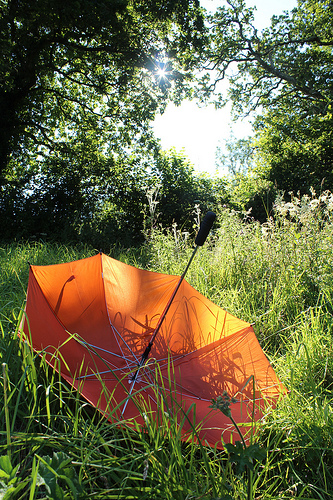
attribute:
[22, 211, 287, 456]
umbrella — open, upside down, orange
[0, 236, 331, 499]
grass — green, nice, thin, tall, high, in picture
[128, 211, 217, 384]
handle — silver, plastic, black, metal, long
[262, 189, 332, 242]
weeds — green, tall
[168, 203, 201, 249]
weeds — green, tall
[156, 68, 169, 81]
sun — bright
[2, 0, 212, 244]
trees — with many leaves, tall, with leaves, green, overgrown, with green leaves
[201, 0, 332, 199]
trees — with many leaves, tall, with leaves, green, overgrown, with green leaves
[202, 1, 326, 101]
tree branch — with green leaves, with green foliage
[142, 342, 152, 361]
plastic — black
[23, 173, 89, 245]
tree — with many leaves, short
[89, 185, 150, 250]
tree — with many leaves, short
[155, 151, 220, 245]
tree — with many leaves, short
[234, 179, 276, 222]
tree — with many leaves, short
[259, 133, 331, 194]
tree — with many leaves, short